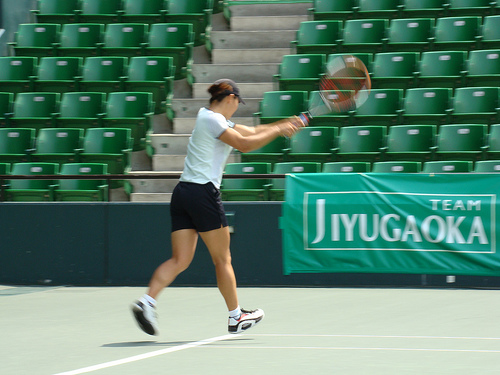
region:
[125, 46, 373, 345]
Tennis player in motion.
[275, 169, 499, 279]
Green sign on the wall.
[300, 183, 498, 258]
Sign that states what team it is.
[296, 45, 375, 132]
Tennis racket in motion.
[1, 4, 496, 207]
Green stadium seats that are empty.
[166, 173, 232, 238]
Black shorts on tennis player.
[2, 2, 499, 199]
Stadium seats have white tags on the back.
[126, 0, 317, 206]
Cement stairs at the stadium.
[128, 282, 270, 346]
Tennis shoes on the player.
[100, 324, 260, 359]
Shadow of tennis player.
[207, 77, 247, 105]
Woman wearing a gray hat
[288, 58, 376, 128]
Woman holding a tennis racket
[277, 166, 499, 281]
Green banner on a wall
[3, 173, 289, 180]
Metal railing on a wall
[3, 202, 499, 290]
Blue padding on a wall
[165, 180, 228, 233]
Woman wearing blue shorts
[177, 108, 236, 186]
Woman wearing a white shirt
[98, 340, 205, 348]
Shadow of a woman on a tennis court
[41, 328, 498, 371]
White lines on a tennis court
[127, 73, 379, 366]
Woman running on a tennis court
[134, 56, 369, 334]
a woman playing tennis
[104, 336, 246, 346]
shadows on the ground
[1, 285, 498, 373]
court is light green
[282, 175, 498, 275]
the banner is green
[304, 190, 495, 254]
the text is white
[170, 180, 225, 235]
woman is wearing shorts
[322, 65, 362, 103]
racket net is red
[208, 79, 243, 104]
hat on woman's head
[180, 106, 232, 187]
a light blue shirt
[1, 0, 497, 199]
a bunch of chairs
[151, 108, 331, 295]
A LADY IS IN THE TENNIS BALL FIELD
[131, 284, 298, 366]
shoes are black and white in color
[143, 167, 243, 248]
pants are balck incolor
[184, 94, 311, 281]
the lady is hitimng a ball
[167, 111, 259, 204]
the blouse is white in color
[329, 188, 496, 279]
the banner is green incolor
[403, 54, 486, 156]
the seats are empty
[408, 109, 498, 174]
the seats ar green in color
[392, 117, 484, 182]
theseats have some white writtngs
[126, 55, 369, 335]
Woman swinging a tennis racket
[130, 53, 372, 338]
Woman holding a tennis racket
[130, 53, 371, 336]
Woman playing tennis on a tennis court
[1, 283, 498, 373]
Green tennis court with white lines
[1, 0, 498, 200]
Green seats in the stands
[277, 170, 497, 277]
Green and white banner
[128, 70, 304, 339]
Woman wearing a white shirt and black shorts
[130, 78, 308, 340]
Woman wearing a black baseball cap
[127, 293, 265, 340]
Black and white tennis shoes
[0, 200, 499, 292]
Dark green tennis court wall padding